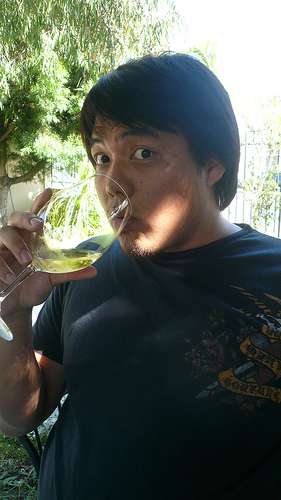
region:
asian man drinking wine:
[11, 39, 261, 403]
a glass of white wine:
[5, 141, 181, 352]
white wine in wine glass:
[7, 157, 191, 364]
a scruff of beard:
[109, 213, 174, 283]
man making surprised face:
[26, 106, 244, 340]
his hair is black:
[33, 94, 279, 350]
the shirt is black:
[12, 113, 280, 434]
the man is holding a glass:
[13, 99, 269, 414]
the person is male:
[22, 113, 265, 403]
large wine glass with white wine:
[1, 170, 129, 343]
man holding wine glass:
[2, 37, 280, 494]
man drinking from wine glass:
[0, 55, 272, 494]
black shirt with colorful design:
[32, 224, 277, 498]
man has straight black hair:
[69, 38, 247, 206]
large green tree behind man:
[3, 5, 171, 304]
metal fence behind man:
[223, 128, 275, 242]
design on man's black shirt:
[187, 272, 279, 417]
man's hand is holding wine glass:
[1, 170, 133, 312]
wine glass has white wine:
[29, 171, 128, 276]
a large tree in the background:
[6, 12, 218, 58]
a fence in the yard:
[245, 134, 275, 225]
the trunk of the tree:
[3, 140, 23, 213]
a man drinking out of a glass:
[77, 51, 237, 250]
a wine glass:
[1, 173, 131, 342]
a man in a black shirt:
[30, 94, 280, 432]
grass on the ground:
[0, 450, 27, 495]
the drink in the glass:
[27, 239, 104, 273]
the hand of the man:
[3, 196, 96, 312]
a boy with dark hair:
[75, 44, 239, 256]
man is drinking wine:
[34, 63, 186, 286]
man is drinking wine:
[66, 135, 177, 284]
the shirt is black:
[47, 257, 234, 466]